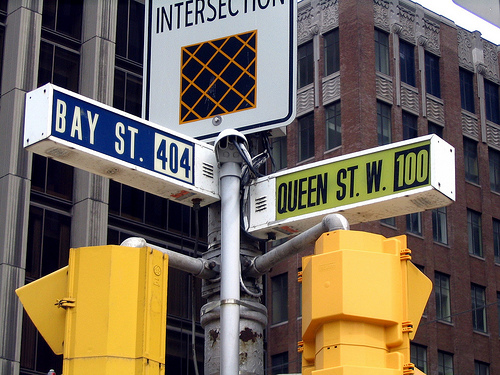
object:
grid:
[176, 30, 261, 127]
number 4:
[157, 139, 167, 170]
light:
[296, 229, 433, 375]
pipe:
[219, 300, 240, 374]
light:
[11, 244, 169, 375]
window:
[397, 38, 417, 88]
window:
[467, 209, 483, 259]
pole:
[218, 164, 241, 374]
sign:
[275, 139, 433, 224]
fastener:
[54, 298, 76, 310]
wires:
[235, 142, 263, 178]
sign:
[142, 0, 296, 144]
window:
[424, 49, 444, 98]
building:
[262, 0, 499, 375]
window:
[373, 26, 391, 74]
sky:
[413, 0, 499, 43]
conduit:
[213, 130, 243, 203]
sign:
[50, 89, 193, 188]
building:
[1, 0, 205, 375]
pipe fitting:
[118, 121, 347, 278]